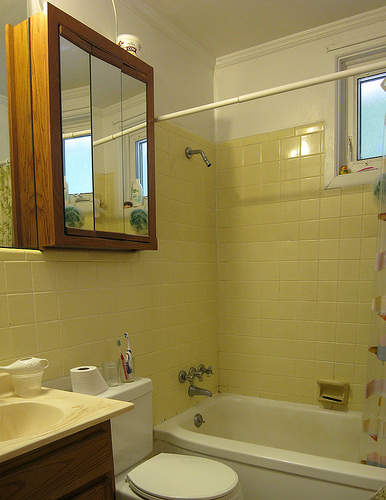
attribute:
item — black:
[323, 395, 342, 406]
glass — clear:
[117, 358, 137, 382]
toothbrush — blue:
[122, 332, 132, 376]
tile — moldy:
[300, 200, 321, 222]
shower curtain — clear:
[360, 81, 385, 466]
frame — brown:
[4, 4, 158, 252]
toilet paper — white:
[70, 364, 108, 394]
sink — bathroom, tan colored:
[2, 403, 62, 444]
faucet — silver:
[178, 369, 197, 386]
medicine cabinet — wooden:
[4, 2, 159, 252]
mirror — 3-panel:
[56, 37, 94, 231]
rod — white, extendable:
[153, 57, 385, 124]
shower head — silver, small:
[183, 146, 210, 167]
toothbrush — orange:
[115, 337, 129, 380]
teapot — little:
[2, 356, 49, 394]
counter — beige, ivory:
[0, 387, 134, 463]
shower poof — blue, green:
[129, 207, 148, 234]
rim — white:
[325, 30, 385, 193]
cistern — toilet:
[74, 377, 156, 473]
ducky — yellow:
[338, 164, 348, 173]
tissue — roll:
[75, 371, 104, 389]